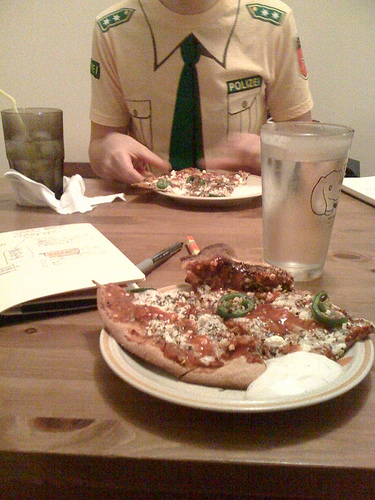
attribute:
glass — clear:
[260, 122, 354, 283]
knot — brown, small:
[31, 416, 98, 434]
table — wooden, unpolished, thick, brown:
[2, 177, 372, 499]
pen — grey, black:
[136, 241, 183, 274]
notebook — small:
[1, 220, 145, 316]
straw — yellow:
[1, 86, 18, 114]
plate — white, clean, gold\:
[98, 280, 372, 413]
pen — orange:
[184, 235, 203, 257]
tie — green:
[169, 36, 210, 171]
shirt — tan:
[89, 1, 313, 170]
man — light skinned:
[89, 0, 313, 184]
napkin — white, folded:
[7, 170, 126, 217]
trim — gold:
[141, 388, 254, 410]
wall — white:
[0, 0, 373, 180]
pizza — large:
[94, 283, 373, 390]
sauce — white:
[246, 349, 345, 401]